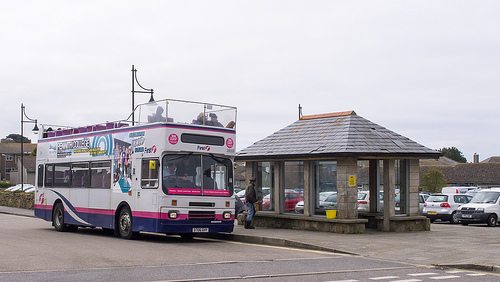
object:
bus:
[34, 98, 235, 243]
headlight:
[170, 212, 177, 218]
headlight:
[224, 213, 232, 220]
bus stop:
[235, 110, 444, 234]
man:
[242, 177, 260, 229]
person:
[206, 112, 224, 127]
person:
[150, 106, 166, 123]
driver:
[163, 163, 187, 181]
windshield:
[163, 152, 234, 198]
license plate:
[192, 228, 209, 233]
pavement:
[293, 257, 372, 282]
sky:
[220, 4, 499, 103]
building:
[0, 141, 35, 186]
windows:
[6, 154, 13, 161]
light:
[32, 119, 40, 135]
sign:
[349, 175, 357, 187]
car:
[421, 193, 473, 226]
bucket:
[325, 210, 336, 219]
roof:
[2, 141, 37, 154]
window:
[165, 99, 236, 131]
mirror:
[149, 160, 156, 170]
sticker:
[168, 133, 179, 146]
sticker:
[226, 138, 234, 149]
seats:
[106, 120, 118, 129]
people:
[192, 112, 209, 126]